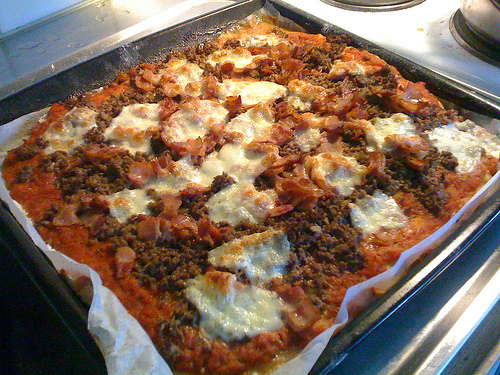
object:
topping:
[387, 154, 454, 214]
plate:
[127, 7, 226, 78]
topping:
[120, 142, 171, 185]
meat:
[381, 133, 461, 215]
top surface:
[0, 0, 236, 93]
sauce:
[217, 21, 323, 44]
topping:
[206, 164, 357, 291]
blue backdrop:
[388, 220, 497, 317]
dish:
[0, 0, 500, 374]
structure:
[449, 0, 500, 67]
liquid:
[18, 37, 45, 52]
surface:
[32, 17, 89, 52]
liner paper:
[84, 283, 174, 374]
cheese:
[100, 174, 175, 223]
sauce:
[3, 153, 227, 373]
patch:
[86, 3, 133, 22]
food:
[4, 15, 498, 373]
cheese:
[207, 228, 293, 288]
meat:
[287, 203, 365, 282]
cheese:
[186, 270, 283, 340]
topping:
[306, 97, 357, 139]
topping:
[161, 71, 237, 112]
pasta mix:
[27, 16, 484, 366]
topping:
[161, 250, 178, 266]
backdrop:
[0, 2, 76, 35]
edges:
[124, 347, 333, 375]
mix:
[11, 23, 451, 345]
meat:
[99, 216, 210, 294]